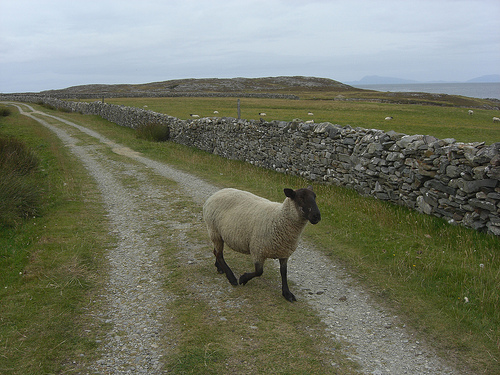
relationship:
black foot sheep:
[282, 280, 288, 295] [202, 189, 318, 301]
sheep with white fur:
[202, 189, 318, 301] [225, 197, 254, 221]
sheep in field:
[257, 104, 319, 118] [324, 99, 380, 122]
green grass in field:
[345, 231, 385, 256] [324, 99, 380, 122]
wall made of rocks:
[368, 144, 444, 192] [453, 175, 498, 204]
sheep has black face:
[202, 189, 318, 301] [294, 188, 321, 222]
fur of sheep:
[225, 197, 254, 221] [202, 189, 318, 301]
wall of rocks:
[368, 144, 444, 192] [453, 175, 498, 204]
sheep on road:
[202, 189, 318, 301] [0, 98, 499, 373]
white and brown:
[267, 220, 294, 246] [305, 190, 312, 202]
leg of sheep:
[280, 269, 290, 302] [202, 189, 318, 301]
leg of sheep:
[240, 271, 260, 285] [202, 189, 318, 301]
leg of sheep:
[220, 255, 237, 287] [202, 189, 318, 301]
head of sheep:
[294, 188, 321, 222] [202, 189, 318, 301]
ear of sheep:
[283, 186, 294, 200] [202, 189, 318, 301]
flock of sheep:
[211, 106, 316, 118] [202, 189, 318, 301]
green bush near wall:
[345, 231, 385, 256] [368, 144, 444, 192]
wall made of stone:
[368, 144, 444, 192] [280, 134, 317, 158]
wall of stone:
[368, 144, 444, 192] [280, 134, 317, 158]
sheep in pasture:
[202, 189, 318, 301] [251, 95, 319, 118]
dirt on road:
[314, 289, 360, 318] [88, 146, 173, 215]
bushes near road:
[1, 136, 39, 212] [88, 146, 173, 215]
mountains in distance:
[354, 72, 495, 102] [345, 56, 499, 104]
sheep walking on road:
[202, 189, 318, 301] [0, 98, 499, 373]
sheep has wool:
[202, 189, 318, 301] [213, 192, 235, 224]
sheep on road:
[202, 189, 318, 301] [88, 146, 173, 215]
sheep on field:
[202, 189, 318, 301] [324, 99, 380, 122]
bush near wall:
[137, 121, 168, 141] [368, 144, 444, 192]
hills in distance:
[125, 76, 346, 95] [345, 56, 499, 104]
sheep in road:
[202, 189, 318, 301] [88, 146, 173, 215]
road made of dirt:
[88, 146, 173, 215] [314, 289, 360, 318]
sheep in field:
[202, 189, 318, 301] [324, 99, 380, 122]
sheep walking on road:
[202, 189, 318, 301] [88, 146, 173, 215]